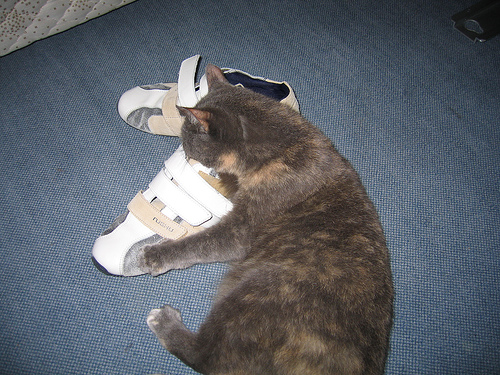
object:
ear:
[174, 104, 216, 134]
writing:
[152, 216, 174, 232]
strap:
[126, 189, 187, 241]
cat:
[134, 62, 397, 375]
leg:
[134, 207, 246, 277]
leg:
[144, 303, 201, 373]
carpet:
[2, 0, 499, 375]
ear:
[203, 63, 233, 93]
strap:
[147, 166, 212, 228]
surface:
[0, 0, 500, 375]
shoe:
[90, 144, 245, 277]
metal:
[451, 0, 500, 43]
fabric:
[0, 0, 136, 57]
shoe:
[115, 54, 303, 138]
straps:
[177, 53, 200, 108]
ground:
[0, 0, 500, 375]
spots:
[15, 44, 19, 49]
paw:
[133, 243, 171, 277]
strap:
[162, 147, 234, 219]